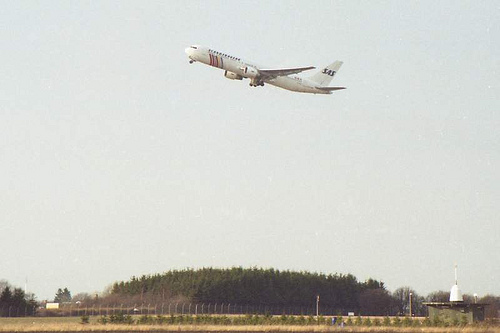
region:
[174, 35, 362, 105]
airplane in the sky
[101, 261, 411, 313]
trees under the airplane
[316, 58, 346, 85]
it says SAS on the airplane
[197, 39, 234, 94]
there are red and blue stripes on the airplane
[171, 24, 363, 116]
the airplane is white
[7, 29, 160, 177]
no clouds in the sky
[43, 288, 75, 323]
small building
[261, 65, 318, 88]
airplane has a big wing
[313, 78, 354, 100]
the airplane has a small wing in the back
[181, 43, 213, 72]
the airplane has the wheel out in front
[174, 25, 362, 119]
A large airplane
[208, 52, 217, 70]
Red stripes on an airplane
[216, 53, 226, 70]
A blue stripe on an airplane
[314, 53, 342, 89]
Numbers on the tail of airplane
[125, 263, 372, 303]
A group of green trees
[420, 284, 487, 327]
An outside building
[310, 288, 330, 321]
A street light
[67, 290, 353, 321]
A long fence around airport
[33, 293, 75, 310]
A building in the background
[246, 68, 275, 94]
Airplanes landing gear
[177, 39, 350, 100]
White airplane with the letters SAS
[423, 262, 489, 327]
Small green building with white top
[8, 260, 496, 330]
Field with trees in the distance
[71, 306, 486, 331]
Line of small green pine trees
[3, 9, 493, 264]
Airplane flying in the sky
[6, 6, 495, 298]
Gray sky with a white airplane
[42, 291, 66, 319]
Small white building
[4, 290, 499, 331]
Fence surrounding an airport runway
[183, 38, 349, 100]
White plane with red, yellow and blue stripes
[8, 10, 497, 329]
Airplane taking off from runway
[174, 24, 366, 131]
a jet plane taking off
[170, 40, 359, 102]
the plane is white with red & blue markings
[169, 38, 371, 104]
the tail says SAS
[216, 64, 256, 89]
the jet engines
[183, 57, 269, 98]
the landing gear is still down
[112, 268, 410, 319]
a thicket of trees off the runway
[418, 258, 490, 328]
runway markers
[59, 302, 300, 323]
a fence is along the side of the runway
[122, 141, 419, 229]
it appears to be a very overcast day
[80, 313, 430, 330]
a line of small evergreens bushes line the runway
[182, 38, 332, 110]
plane taking off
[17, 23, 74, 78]
white clouds in blue sky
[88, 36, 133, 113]
white clouds in blue sky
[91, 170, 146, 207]
white clouds in blue sky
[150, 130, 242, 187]
white clouds in blue sky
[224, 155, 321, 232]
white clouds in blue sky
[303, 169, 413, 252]
white clouds in blue sky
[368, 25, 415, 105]
white clouds in blue sky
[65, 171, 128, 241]
white clouds in blue sky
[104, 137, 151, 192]
white clouds in blue sky